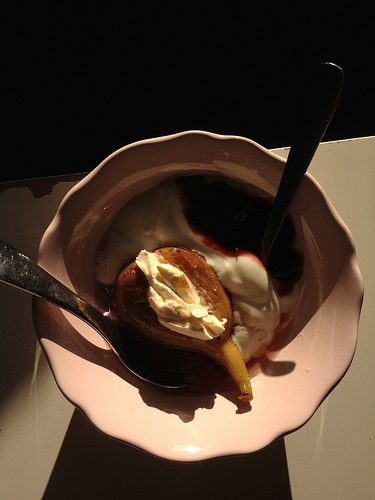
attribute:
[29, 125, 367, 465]
bowl — pink, white, round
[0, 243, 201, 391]
spoon — metal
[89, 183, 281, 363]
yogurt — white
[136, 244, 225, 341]
filling — white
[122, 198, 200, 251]
cream — white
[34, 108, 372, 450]
bowl — glass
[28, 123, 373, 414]
bowl — glass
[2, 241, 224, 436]
spoon — silver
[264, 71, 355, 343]
spoon — silver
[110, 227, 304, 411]
food — round 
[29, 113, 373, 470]
round bowl — white , round  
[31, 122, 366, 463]
white bowl — white 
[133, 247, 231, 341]
cream — white